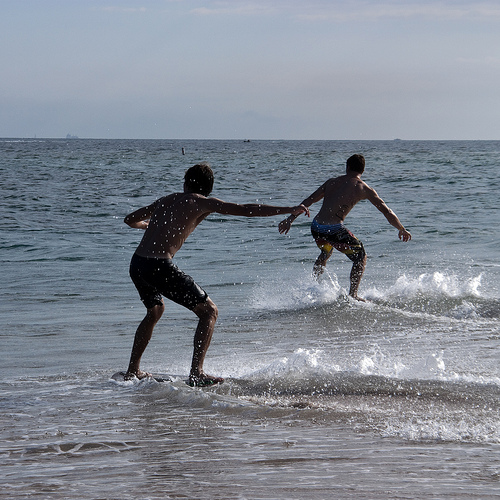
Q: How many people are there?
A: Two.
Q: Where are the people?
A: In the ocean.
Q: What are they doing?
A: Riding boogie boards.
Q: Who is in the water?
A: Two men.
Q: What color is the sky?
A: Grey.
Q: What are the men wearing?
A: Swim trunks.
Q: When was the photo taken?
A: During the day.